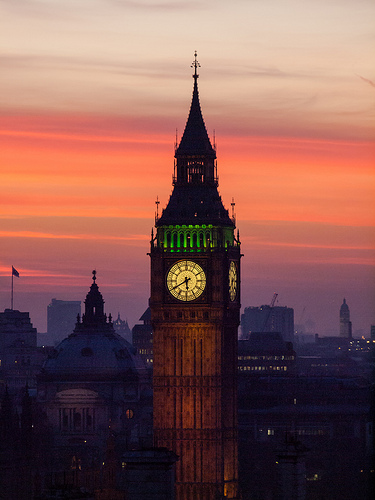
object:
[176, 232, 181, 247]
light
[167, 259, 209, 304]
clock